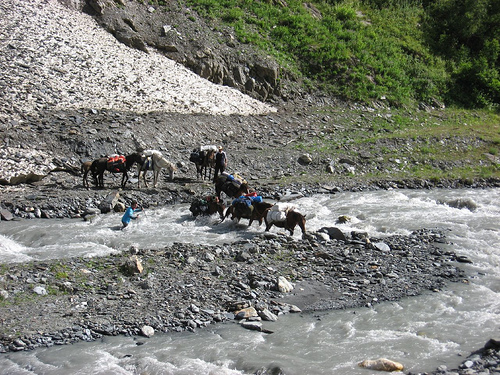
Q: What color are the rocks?
A: Gray.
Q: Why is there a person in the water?
A: To guide the animals.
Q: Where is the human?
A: In the water.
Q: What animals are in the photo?
A: Horses.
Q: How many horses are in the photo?
A: 7.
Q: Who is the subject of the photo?
A: The animals.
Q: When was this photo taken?
A: During the day.